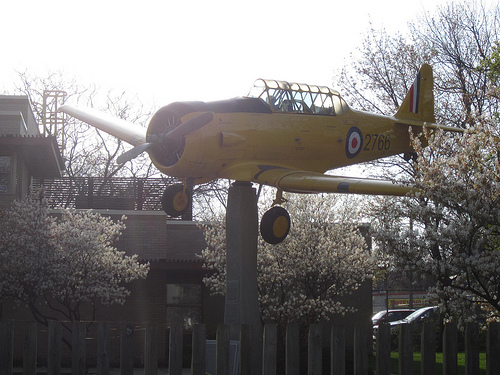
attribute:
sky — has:
[11, 0, 497, 215]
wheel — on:
[259, 202, 293, 248]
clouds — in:
[5, 0, 428, 86]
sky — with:
[8, 0, 499, 88]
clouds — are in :
[12, 0, 472, 90]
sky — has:
[8, 0, 488, 128]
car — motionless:
[378, 306, 495, 348]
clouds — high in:
[54, 16, 151, 53]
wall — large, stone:
[41, 210, 198, 265]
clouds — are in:
[12, 15, 135, 73]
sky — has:
[4, 0, 330, 55]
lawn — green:
[377, 350, 490, 373]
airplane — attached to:
[46, 54, 448, 259]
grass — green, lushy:
[373, 329, 498, 371]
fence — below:
[2, 315, 499, 372]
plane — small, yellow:
[53, 60, 483, 226]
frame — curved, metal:
[243, 75, 351, 117]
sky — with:
[0, 21, 496, 243]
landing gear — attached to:
[258, 195, 300, 244]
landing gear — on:
[156, 177, 203, 214]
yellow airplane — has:
[55, 58, 470, 248]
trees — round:
[2, 7, 499, 324]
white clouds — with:
[330, 2, 358, 29]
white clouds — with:
[260, 38, 289, 62]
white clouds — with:
[155, 35, 180, 56]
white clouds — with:
[110, 8, 142, 48]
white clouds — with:
[30, 20, 64, 47]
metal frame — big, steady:
[39, 83, 66, 138]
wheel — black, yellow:
[260, 206, 291, 244]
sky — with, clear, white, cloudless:
[3, 17, 498, 224]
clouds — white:
[37, 46, 276, 80]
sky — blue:
[29, 7, 444, 108]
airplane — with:
[47, 66, 469, 246]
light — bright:
[41, 0, 287, 79]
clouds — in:
[24, 10, 362, 79]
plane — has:
[90, 57, 481, 248]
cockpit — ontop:
[256, 76, 343, 116]